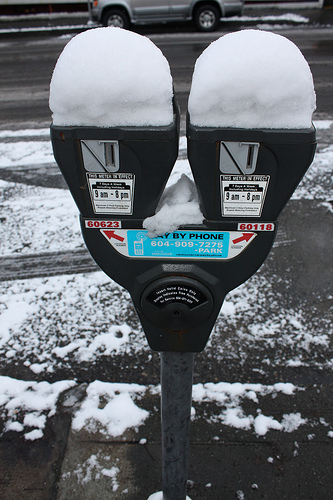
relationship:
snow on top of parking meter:
[50, 28, 176, 126] [47, 26, 316, 353]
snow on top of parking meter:
[189, 29, 315, 130] [47, 26, 316, 353]